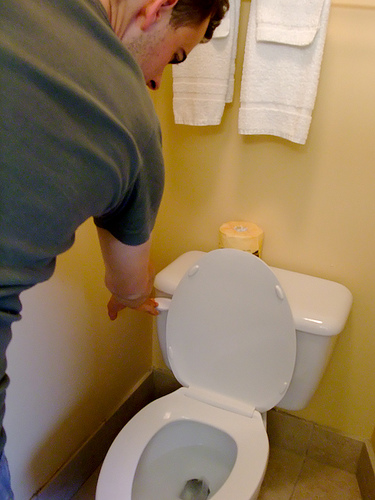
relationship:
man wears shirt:
[0, 0, 228, 498] [6, 6, 162, 317]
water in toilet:
[150, 445, 220, 494] [89, 245, 357, 498]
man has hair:
[0, 0, 228, 498] [172, 5, 218, 25]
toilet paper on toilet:
[217, 219, 265, 262] [89, 245, 357, 498]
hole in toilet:
[174, 477, 212, 498] [89, 245, 357, 498]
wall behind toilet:
[277, 163, 358, 257] [89, 245, 357, 498]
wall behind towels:
[277, 163, 358, 257] [220, 2, 328, 144]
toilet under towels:
[89, 245, 357, 498] [220, 2, 328, 144]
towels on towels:
[236, 0, 329, 146] [220, 2, 328, 144]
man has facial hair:
[0, 0, 228, 498] [131, 26, 167, 78]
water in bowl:
[150, 445, 222, 496] [134, 408, 250, 498]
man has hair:
[0, 0, 228, 498] [172, 0, 231, 40]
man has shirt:
[6, 2, 190, 498] [6, 6, 162, 317]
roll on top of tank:
[215, 214, 266, 260] [150, 250, 349, 410]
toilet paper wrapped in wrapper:
[217, 219, 265, 262] [217, 220, 263, 259]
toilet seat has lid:
[97, 385, 268, 498] [164, 249, 296, 417]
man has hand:
[0, 0, 228, 498] [107, 294, 158, 321]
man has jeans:
[0, 0, 228, 498] [1, 440, 15, 499]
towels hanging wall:
[236, 0, 329, 146] [307, 152, 342, 230]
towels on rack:
[154, 12, 314, 152] [151, 22, 368, 311]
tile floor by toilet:
[283, 447, 341, 488] [89, 245, 357, 498]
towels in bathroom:
[180, 77, 318, 133] [7, 2, 373, 498]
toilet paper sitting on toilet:
[217, 219, 265, 262] [89, 245, 357, 498]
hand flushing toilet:
[100, 293, 160, 323] [89, 245, 357, 498]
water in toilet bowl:
[150, 445, 220, 494] [95, 244, 354, 498]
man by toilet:
[0, 0, 228, 498] [89, 245, 357, 498]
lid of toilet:
[164, 249, 296, 417] [89, 245, 357, 498]